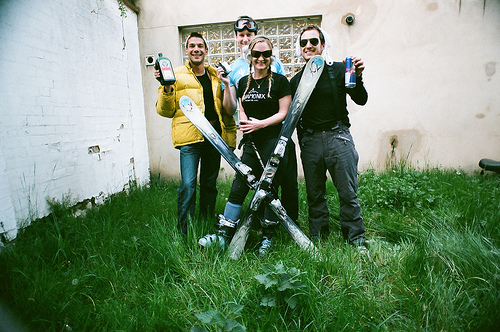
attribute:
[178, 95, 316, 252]
skis — big, in front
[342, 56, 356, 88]
red bull — canned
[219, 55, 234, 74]
bottle — liquor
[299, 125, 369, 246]
pants — gray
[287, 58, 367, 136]
shirt — black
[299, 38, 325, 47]
sunglasses — pair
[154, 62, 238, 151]
jacket — yellow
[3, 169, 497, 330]
area — grassy, green, tall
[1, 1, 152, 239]
wall — white, brick